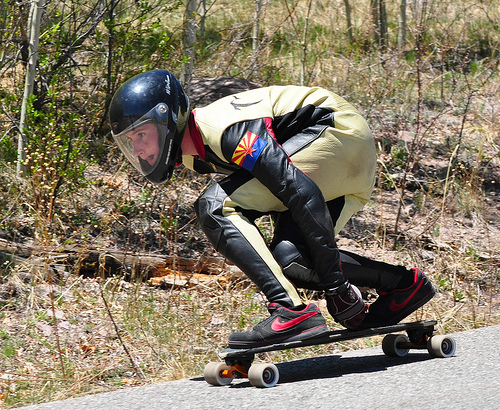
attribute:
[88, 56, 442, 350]
skateboarder — kneeling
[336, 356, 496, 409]
road — paved, asphalt, gray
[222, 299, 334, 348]
shoe — black, red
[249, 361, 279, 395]
wheel — white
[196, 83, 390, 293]
suit — leather, yellow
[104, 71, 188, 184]
helmet — black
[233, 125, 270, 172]
patch — blue, yellow, colorful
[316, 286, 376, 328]
glove — gray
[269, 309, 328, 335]
logo — red, nike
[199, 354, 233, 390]
wheel — white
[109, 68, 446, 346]
woman — skateboarding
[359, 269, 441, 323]
shoe — black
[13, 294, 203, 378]
foilage — dry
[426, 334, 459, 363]
wheel — white